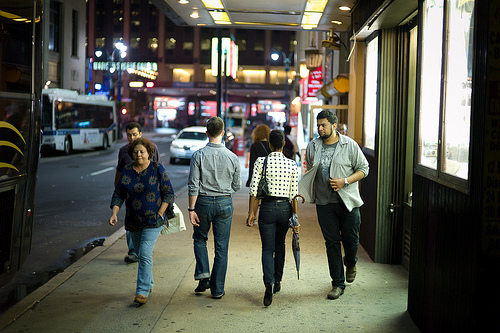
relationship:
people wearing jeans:
[186, 116, 241, 301] [190, 186, 240, 311]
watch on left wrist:
[188, 205, 196, 211] [187, 207, 195, 212]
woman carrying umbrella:
[244, 123, 309, 311] [287, 187, 316, 280]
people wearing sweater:
[107, 136, 175, 309] [127, 177, 158, 222]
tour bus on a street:
[40, 86, 120, 154] [19, 127, 196, 283]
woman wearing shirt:
[244, 123, 309, 311] [246, 148, 303, 201]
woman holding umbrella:
[244, 123, 309, 311] [288, 194, 303, 276]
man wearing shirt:
[185, 115, 243, 300] [185, 143, 245, 196]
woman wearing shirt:
[103, 130, 179, 305] [115, 159, 171, 216]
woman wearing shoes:
[103, 130, 179, 305] [109, 277, 166, 316]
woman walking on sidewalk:
[244, 123, 309, 311] [192, 298, 380, 330]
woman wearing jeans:
[103, 130, 179, 305] [128, 228, 162, 297]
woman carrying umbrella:
[103, 130, 179, 305] [282, 198, 317, 285]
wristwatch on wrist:
[186, 204, 199, 214] [178, 205, 215, 224]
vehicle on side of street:
[168, 125, 226, 165] [3, 129, 246, 315]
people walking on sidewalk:
[296, 111, 364, 302] [0, 139, 410, 330]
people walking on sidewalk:
[247, 130, 299, 315] [0, 139, 410, 330]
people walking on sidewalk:
[186, 116, 241, 301] [0, 139, 410, 330]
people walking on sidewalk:
[106, 133, 175, 309] [0, 139, 410, 330]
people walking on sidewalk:
[112, 121, 149, 269] [0, 139, 410, 330]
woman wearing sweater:
[103, 130, 179, 305] [110, 165, 168, 230]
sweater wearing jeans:
[110, 165, 168, 230] [117, 225, 164, 297]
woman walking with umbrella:
[244, 123, 309, 311] [282, 187, 323, 290]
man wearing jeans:
[185, 115, 243, 300] [171, 175, 242, 305]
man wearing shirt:
[185, 115, 243, 300] [187, 135, 242, 204]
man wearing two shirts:
[291, 100, 375, 298] [305, 136, 366, 212]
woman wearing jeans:
[103, 130, 179, 305] [125, 221, 164, 298]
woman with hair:
[103, 130, 179, 305] [125, 136, 153, 163]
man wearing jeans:
[185, 115, 243, 300] [188, 194, 248, 266]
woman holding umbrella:
[244, 123, 309, 311] [281, 196, 308, 281]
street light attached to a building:
[306, 45, 324, 71] [149, 0, 499, 331]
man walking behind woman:
[115, 124, 145, 268] [103, 130, 179, 305]